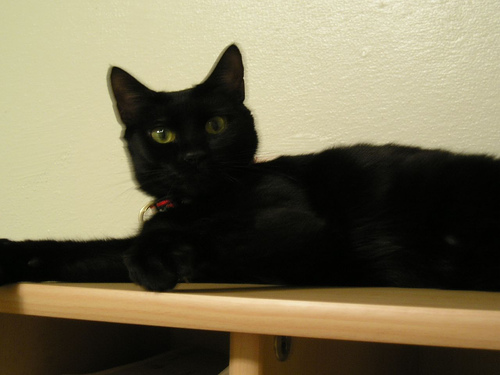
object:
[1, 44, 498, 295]
cat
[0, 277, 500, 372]
shelf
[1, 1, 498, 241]
wall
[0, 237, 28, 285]
right paw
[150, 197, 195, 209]
collar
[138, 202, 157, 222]
metal ring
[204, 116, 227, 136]
left eye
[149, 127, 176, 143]
right eye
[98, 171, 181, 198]
whiskers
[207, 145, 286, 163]
whiskers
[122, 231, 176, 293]
left paw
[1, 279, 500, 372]
table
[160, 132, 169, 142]
pupil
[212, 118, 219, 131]
pupil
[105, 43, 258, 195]
head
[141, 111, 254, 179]
face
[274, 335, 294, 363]
shelf support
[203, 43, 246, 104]
left ear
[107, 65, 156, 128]
right ear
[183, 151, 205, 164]
nose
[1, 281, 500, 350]
edge